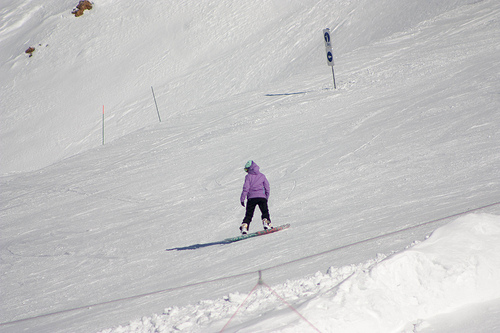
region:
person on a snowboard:
[221, 156, 289, 243]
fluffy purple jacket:
[233, 161, 275, 205]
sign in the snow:
[319, 25, 340, 90]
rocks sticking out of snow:
[23, 0, 92, 59]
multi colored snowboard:
[223, 219, 291, 249]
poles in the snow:
[98, 83, 163, 145]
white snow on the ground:
[2, 2, 498, 331]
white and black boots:
[235, 215, 271, 236]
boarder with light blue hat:
[242, 155, 258, 170]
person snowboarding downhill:
[215, 152, 283, 254]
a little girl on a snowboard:
[222, 147, 291, 250]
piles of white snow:
[214, 264, 470, 317]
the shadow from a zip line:
[156, 257, 358, 329]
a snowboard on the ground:
[203, 228, 292, 245]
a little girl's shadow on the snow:
[165, 239, 211, 258]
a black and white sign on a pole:
[312, 23, 345, 97]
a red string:
[273, 288, 320, 330]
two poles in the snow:
[75, 77, 211, 144]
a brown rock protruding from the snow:
[62, 0, 105, 25]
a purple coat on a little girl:
[235, 174, 272, 201]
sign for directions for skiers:
[320, 25, 337, 91]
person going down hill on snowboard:
[190, 83, 321, 303]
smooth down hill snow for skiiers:
[371, 72, 479, 191]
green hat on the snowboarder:
[243, 160, 253, 171]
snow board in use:
[220, 221, 291, 249]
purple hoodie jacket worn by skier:
[238, 164, 268, 202]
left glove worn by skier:
[239, 198, 245, 207]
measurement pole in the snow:
[99, 104, 108, 154]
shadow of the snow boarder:
[164, 237, 231, 253]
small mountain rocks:
[19, 0, 91, 60]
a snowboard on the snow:
[175, 136, 362, 255]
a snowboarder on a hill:
[118, 95, 478, 285]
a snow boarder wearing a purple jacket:
[179, 127, 304, 252]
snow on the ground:
[308, 85, 424, 227]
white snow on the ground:
[354, 106, 475, 231]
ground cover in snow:
[364, 111, 451, 233]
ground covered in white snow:
[341, 107, 496, 309]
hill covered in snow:
[236, 74, 498, 241]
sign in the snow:
[298, 14, 378, 110]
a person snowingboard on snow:
[215, 120, 326, 275]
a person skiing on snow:
[198, 125, 365, 268]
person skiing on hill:
[185, 107, 386, 282]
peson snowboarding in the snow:
[194, 137, 306, 253]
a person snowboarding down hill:
[165, 65, 468, 282]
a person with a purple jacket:
[204, 142, 297, 238]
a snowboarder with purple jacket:
[194, 143, 301, 249]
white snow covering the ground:
[290, 91, 499, 253]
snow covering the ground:
[327, 127, 489, 273]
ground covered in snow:
[310, 134, 460, 284]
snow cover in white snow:
[312, 96, 499, 262]